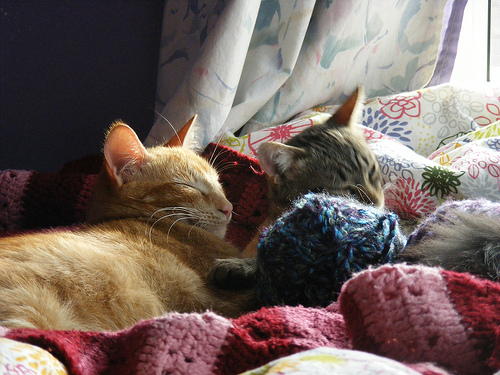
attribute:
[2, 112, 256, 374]
cat — brown, sleeping, gold, orange, white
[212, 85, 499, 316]
cat — striped, gray, tiger gray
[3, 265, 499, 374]
blanket — crocheted, pink, floral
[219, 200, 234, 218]
nose — pink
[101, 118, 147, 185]
ear — pink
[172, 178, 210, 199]
eye — closed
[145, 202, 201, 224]
whisker — white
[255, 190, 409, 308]
yarn — purple, blue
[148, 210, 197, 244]
whisker — white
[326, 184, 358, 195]
eye — closed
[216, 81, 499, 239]
blanket — floral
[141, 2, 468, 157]
curtain — flowery, white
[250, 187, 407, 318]
blanket — blue